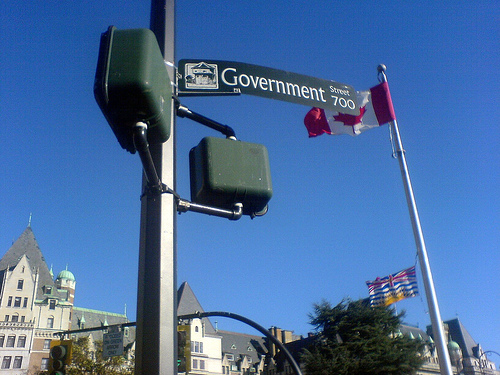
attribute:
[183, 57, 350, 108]
sign — green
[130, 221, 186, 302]
pole — black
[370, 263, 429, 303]
flag — red, white, blue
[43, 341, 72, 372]
lights — green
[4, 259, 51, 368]
buildinbg — white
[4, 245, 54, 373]
building — white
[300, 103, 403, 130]
flag — canadian, white, red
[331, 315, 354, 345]
leavs — green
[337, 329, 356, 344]
tree — green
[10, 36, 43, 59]
sky — blue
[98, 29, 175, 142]
signal — green, square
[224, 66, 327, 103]
word — white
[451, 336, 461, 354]
dome — green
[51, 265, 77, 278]
dome — green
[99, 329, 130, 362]
sign — white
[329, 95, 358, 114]
number — 700, white